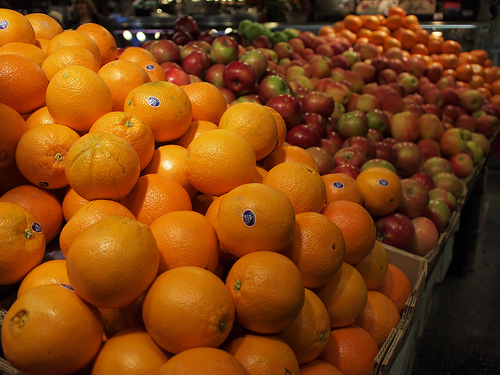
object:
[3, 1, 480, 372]
marketplace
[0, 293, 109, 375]
corner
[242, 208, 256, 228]
sticker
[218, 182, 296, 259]
orange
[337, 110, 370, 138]
apple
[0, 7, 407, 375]
oranges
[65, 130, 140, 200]
orange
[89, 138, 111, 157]
butt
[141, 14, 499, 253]
apples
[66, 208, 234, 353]
three oranges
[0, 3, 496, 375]
fruit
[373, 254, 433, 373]
box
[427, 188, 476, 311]
box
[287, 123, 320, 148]
apple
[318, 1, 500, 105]
oranges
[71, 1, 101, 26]
woman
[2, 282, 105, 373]
orange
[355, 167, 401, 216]
oranges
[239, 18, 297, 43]
five apples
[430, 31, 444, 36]
light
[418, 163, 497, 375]
concrete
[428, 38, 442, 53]
orange